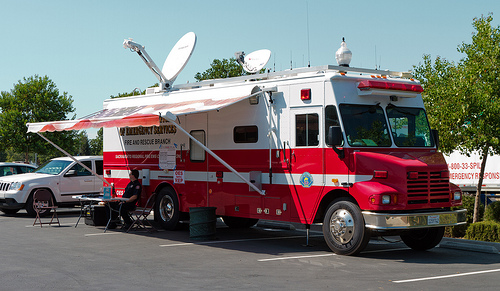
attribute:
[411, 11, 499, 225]
tree — green, tall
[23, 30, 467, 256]
ambulance — parked, red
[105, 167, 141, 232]
man — sitting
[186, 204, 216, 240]
trash — green, small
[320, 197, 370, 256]
tire — black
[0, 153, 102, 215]
car — white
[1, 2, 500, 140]
sky — clear, cloudless, blue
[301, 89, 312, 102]
light — red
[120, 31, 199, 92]
dish — large, white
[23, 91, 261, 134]
canopy — red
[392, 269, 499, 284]
line — white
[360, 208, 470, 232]
bumper — metal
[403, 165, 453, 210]
grill — red